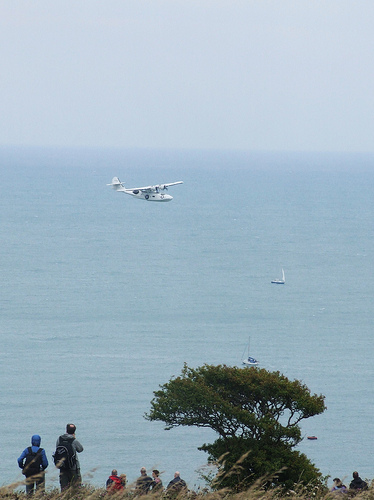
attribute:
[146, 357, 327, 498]
tree — small, green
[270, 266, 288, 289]
sailboat — small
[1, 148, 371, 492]
water — blue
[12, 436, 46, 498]
person — standing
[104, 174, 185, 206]
plane — small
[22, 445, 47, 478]
backpack — black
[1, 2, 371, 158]
sky — blue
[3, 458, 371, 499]
grass — dried, brown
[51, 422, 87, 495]
person — standing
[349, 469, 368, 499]
person — standing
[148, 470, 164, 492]
person — standing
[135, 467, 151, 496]
person — standing, bald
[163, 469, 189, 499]
person — bald